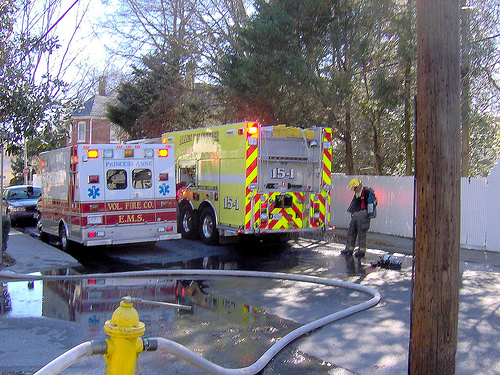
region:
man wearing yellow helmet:
[350, 181, 360, 184]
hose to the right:
[305, 301, 335, 326]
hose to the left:
[47, 340, 82, 370]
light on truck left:
[241, 118, 261, 138]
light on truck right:
[321, 120, 336, 145]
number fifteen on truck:
[267, 164, 289, 182]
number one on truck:
[290, 165, 296, 182]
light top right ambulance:
[155, 144, 173, 159]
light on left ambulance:
[81, 145, 105, 164]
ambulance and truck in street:
[50, 110, 342, 267]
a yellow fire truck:
[171, 120, 331, 241]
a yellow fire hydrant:
[98, 298, 148, 371]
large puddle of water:
[4, 283, 284, 362]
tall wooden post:
[410, 0, 464, 373]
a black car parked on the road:
[2, 183, 44, 225]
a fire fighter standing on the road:
[340, 177, 380, 258]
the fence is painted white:
[328, 172, 498, 249]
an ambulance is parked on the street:
[36, 140, 180, 248]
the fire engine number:
[268, 165, 295, 179]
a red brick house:
[70, 117, 130, 143]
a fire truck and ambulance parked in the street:
[21, 103, 347, 321]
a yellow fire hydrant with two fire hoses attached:
[68, 292, 176, 374]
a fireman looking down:
[333, 173, 380, 261]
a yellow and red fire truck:
[178, 120, 342, 249]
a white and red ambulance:
[29, 130, 184, 258]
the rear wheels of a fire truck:
[178, 199, 218, 244]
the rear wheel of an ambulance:
[52, 219, 75, 249]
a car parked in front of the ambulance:
[1, 178, 45, 230]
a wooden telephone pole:
[387, 4, 481, 374]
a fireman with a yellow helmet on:
[339, 170, 369, 207]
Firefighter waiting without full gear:
[342, 178, 377, 260]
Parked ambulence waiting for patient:
[34, 139, 181, 254]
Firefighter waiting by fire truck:
[175, 116, 380, 258]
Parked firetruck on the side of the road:
[181, 115, 336, 257]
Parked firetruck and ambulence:
[30, 120, 338, 256]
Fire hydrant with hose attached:
[95, 293, 212, 373]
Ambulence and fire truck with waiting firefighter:
[33, 115, 382, 267]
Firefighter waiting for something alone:
[337, 174, 381, 261]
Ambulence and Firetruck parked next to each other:
[28, 117, 339, 252]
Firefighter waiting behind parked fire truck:
[180, 116, 380, 261]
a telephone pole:
[408, 3, 467, 373]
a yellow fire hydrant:
[96, 291, 136, 373]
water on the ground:
[11, 249, 258, 355]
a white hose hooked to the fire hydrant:
[148, 248, 386, 374]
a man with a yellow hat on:
[343, 172, 381, 258]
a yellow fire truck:
[173, 132, 334, 227]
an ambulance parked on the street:
[38, 135, 186, 247]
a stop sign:
[19, 166, 35, 177]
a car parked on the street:
[6, 183, 45, 223]